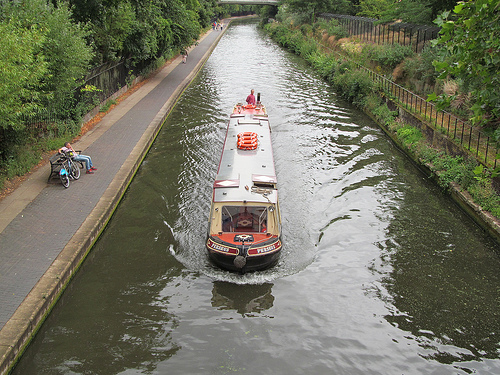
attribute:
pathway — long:
[1, 12, 241, 354]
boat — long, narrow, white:
[200, 93, 290, 276]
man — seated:
[56, 141, 96, 174]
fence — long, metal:
[275, 17, 487, 176]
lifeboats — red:
[236, 129, 259, 151]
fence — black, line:
[289, 7, 499, 211]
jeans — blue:
[72, 152, 96, 176]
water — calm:
[318, 169, 413, 286]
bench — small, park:
[33, 117, 97, 186]